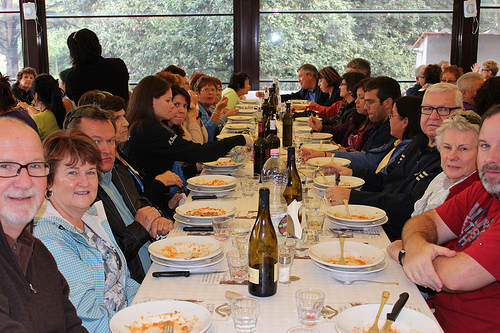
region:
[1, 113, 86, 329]
this is a person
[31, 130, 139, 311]
this is a person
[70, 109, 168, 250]
this is a person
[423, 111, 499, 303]
this is a person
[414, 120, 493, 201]
this is a person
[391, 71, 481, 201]
this is a person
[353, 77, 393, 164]
this is a person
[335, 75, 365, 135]
this is a person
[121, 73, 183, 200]
this is a person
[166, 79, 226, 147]
this is a person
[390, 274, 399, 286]
part of a table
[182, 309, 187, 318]
part of a plate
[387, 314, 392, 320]
part of a knife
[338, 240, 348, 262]
part of a plate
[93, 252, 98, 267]
part of a shirt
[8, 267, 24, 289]
part of a sweater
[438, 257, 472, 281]
part of an elbow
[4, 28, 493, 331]
lots of happy people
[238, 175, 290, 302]
a bottle of wine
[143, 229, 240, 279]
a dirty white plate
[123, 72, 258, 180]
a woman reaching for something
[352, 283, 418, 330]
a knife and fork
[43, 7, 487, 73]
windows with brown trim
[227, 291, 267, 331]
a small glass of water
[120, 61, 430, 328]
a large table with food